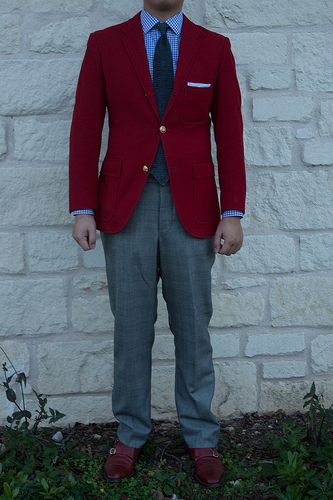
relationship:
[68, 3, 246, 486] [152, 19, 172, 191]
man wearing tie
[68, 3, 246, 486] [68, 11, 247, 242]
man wearing a coat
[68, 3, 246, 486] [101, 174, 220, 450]
man wearing pants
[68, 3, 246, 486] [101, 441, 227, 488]
man wearing shoes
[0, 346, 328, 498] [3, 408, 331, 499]
vegetation growing on ground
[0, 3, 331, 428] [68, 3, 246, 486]
wall behind man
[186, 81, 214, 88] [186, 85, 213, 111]
card in pocket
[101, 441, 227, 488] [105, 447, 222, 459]
shoes have buckles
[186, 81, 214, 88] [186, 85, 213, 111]
handkerchief in pocket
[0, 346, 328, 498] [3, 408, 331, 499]
vegetation on ground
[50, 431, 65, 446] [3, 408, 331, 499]
rock sitting on ground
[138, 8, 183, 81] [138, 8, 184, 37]
shirt has a collar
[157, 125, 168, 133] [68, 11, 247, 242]
button on coat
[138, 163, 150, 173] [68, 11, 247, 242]
button on coat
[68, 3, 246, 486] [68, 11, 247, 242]
man wearing coat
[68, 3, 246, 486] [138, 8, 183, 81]
man wearing a shirt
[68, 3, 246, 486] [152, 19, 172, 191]
man wearing a tie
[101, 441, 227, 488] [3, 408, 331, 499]
shoes are on ground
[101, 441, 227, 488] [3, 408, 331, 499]
shoes are standing on ground